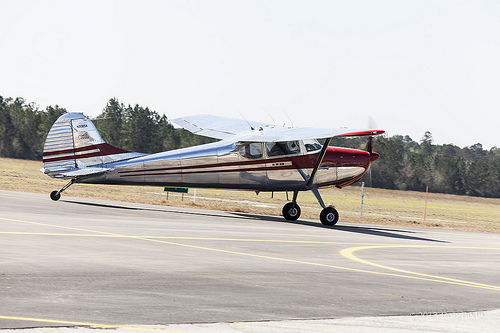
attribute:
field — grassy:
[0, 157, 498, 236]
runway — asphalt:
[1, 189, 499, 330]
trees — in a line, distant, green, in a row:
[0, 95, 499, 198]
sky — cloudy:
[0, 2, 499, 153]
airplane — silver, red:
[43, 112, 386, 226]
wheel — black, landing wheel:
[282, 202, 302, 219]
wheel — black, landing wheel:
[320, 206, 340, 226]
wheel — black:
[49, 189, 61, 200]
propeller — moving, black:
[367, 110, 377, 207]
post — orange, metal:
[423, 186, 431, 223]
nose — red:
[329, 145, 380, 184]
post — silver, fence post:
[358, 180, 367, 220]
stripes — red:
[118, 155, 292, 178]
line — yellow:
[3, 214, 472, 287]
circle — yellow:
[339, 242, 499, 293]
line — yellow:
[0, 229, 430, 249]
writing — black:
[270, 159, 287, 168]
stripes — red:
[41, 143, 101, 163]